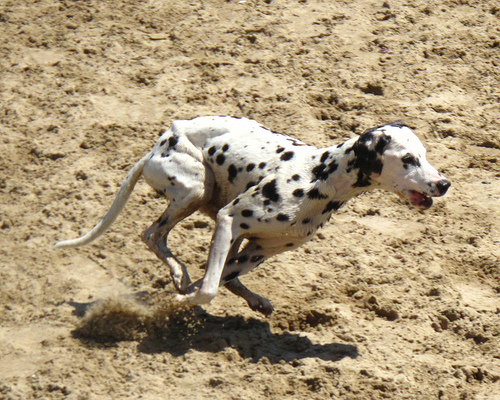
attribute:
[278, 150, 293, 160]
spot — black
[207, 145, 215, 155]
spot — black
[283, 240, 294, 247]
spot — black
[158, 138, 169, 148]
spot — black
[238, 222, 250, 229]
spot — black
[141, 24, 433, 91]
dirt — dry, brown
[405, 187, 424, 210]
tongue — orange, small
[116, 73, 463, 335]
dog — white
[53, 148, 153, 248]
tail — long, white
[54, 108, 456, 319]
dog — white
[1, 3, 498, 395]
dirt — dry, brown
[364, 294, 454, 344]
dirt — brown, dry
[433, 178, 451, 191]
nose — black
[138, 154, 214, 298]
leg — back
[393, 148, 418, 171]
spot — black